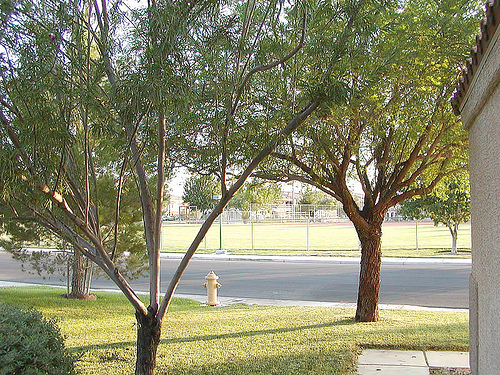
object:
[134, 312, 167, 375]
tree trunk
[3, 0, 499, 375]
photo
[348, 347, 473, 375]
path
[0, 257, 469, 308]
surface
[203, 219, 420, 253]
fence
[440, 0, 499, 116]
roof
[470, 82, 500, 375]
wall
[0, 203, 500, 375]
field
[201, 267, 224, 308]
hydrant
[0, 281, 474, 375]
grass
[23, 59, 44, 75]
leaves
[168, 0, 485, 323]
tree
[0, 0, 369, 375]
tree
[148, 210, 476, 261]
grass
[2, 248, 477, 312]
road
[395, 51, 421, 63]
leaves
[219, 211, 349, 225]
fence